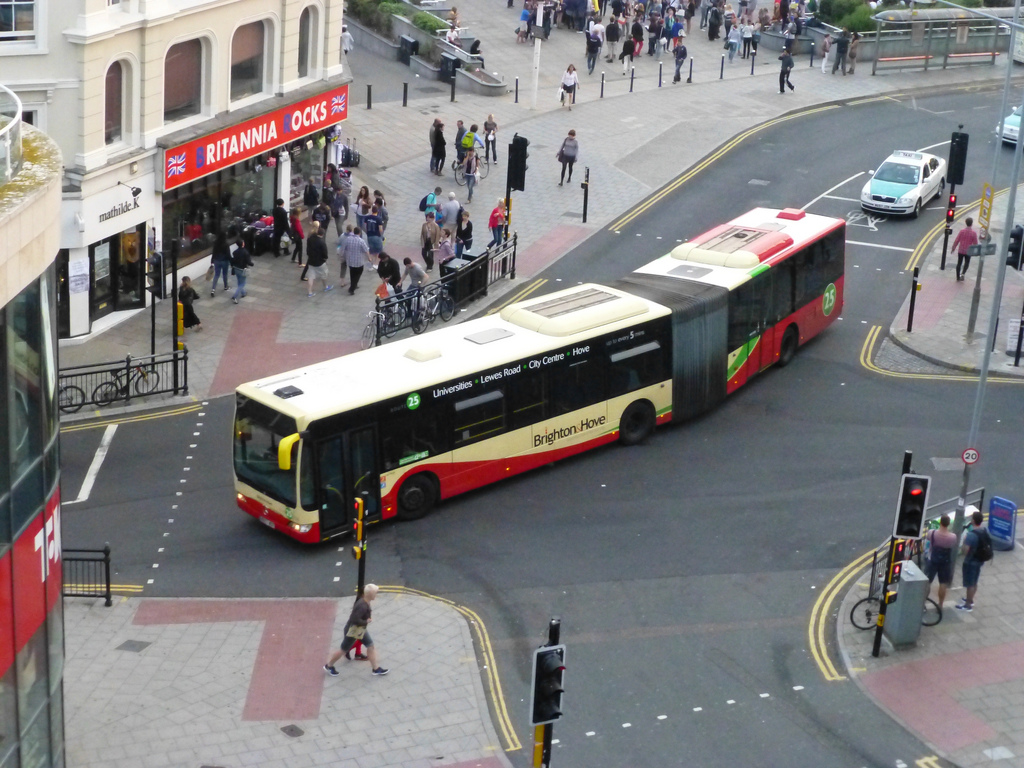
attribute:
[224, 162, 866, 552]
city bus — double long, accordianed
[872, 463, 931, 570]
lights — red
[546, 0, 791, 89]
street — pedestrian only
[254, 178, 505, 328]
people — enjoying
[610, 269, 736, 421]
accordion —  bus'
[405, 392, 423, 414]
circle —  small,  green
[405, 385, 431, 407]
circle —  green,  big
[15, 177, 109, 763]
building — side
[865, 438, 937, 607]
light — red, stop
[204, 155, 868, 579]
bus — turning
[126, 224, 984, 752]
street — new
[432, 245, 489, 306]
trashcans — black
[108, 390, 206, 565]
line — white, dotted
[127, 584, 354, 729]
bricks — red, an L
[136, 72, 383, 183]
red sign — reading Brittannia Rocks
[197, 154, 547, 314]
people — outdoors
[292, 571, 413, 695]
people — outdoors